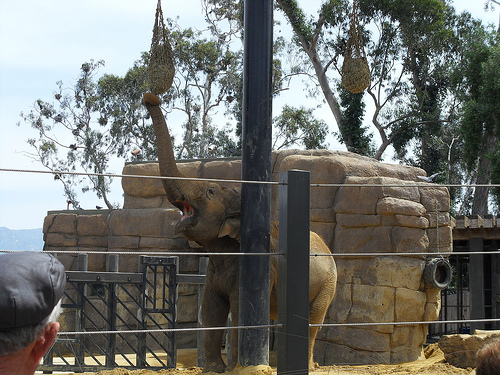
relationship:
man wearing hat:
[5, 359, 43, 371] [1, 256, 59, 350]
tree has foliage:
[320, 120, 425, 164] [387, 7, 433, 53]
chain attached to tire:
[414, 185, 444, 252] [418, 251, 464, 297]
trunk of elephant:
[139, 89, 194, 200] [128, 97, 327, 362]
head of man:
[3, 356, 18, 364] [5, 359, 43, 371]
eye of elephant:
[203, 188, 223, 203] [128, 97, 327, 362]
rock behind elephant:
[325, 300, 430, 366] [128, 97, 327, 362]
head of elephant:
[3, 356, 18, 364] [128, 97, 327, 362]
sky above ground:
[42, 17, 92, 35] [407, 354, 431, 366]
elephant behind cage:
[128, 97, 327, 362] [175, 247, 197, 367]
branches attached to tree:
[346, 62, 428, 131] [320, 120, 425, 164]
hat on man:
[1, 256, 59, 350] [5, 359, 43, 371]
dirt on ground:
[328, 362, 354, 374] [407, 354, 431, 366]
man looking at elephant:
[5, 359, 43, 371] [128, 97, 327, 362]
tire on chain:
[418, 251, 464, 297] [414, 185, 444, 252]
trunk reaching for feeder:
[139, 89, 194, 200] [125, 28, 201, 92]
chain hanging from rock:
[414, 185, 444, 252] [325, 300, 430, 366]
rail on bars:
[137, 251, 158, 275] [64, 278, 181, 367]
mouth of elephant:
[173, 201, 199, 225] [128, 97, 327, 362]